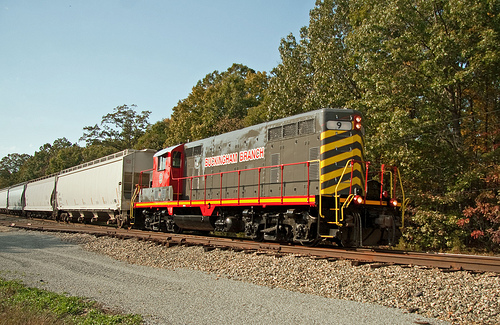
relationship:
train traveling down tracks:
[1, 108, 410, 248] [1, 210, 499, 274]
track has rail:
[1, 210, 499, 274] [343, 249, 499, 271]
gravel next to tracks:
[82, 236, 498, 323] [1, 210, 499, 274]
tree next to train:
[170, 64, 262, 148] [1, 108, 410, 248]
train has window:
[1, 108, 410, 248] [156, 156, 169, 171]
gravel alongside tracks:
[82, 236, 498, 323] [1, 210, 499, 274]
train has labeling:
[1, 108, 410, 248] [204, 146, 267, 165]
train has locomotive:
[1, 108, 410, 248] [127, 106, 405, 249]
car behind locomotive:
[57, 147, 154, 221] [127, 106, 405, 249]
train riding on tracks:
[1, 108, 410, 248] [1, 210, 499, 274]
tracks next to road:
[1, 210, 499, 274] [2, 229, 453, 324]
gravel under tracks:
[388, 261, 400, 268] [1, 210, 499, 274]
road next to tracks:
[2, 229, 453, 324] [1, 210, 499, 274]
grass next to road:
[1, 278, 145, 324] [2, 229, 453, 324]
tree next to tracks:
[350, 5, 499, 170] [1, 210, 499, 274]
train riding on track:
[1, 108, 410, 248] [1, 210, 499, 274]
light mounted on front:
[355, 123, 363, 131] [325, 107, 405, 247]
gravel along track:
[82, 236, 498, 323] [1, 210, 499, 274]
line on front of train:
[339, 195, 402, 209] [1, 108, 410, 248]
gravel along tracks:
[82, 236, 498, 323] [1, 210, 499, 274]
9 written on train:
[336, 120, 342, 129] [1, 108, 410, 248]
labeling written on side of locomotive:
[204, 146, 267, 165] [127, 106, 405, 249]